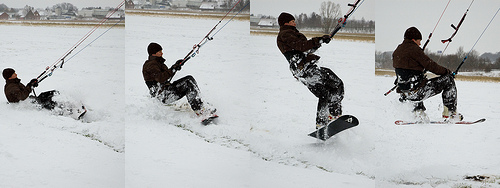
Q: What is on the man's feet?
A: Snowboard.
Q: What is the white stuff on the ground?
A: Snow.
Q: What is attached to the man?
A: Harness.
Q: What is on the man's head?
A: Hat.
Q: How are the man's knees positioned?
A: Bent.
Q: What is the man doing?
A: Snowboarding.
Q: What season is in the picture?
A: Winter.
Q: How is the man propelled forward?
A: Gravity and a kite.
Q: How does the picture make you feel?
A: Excited.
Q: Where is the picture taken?
A: A ski resort.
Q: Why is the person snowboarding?
A: It's fun.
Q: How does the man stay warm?
A: A snowsuit.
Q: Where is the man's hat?
A: On his head.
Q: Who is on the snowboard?
A: A man.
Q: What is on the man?
A: Snow.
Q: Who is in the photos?
A: The same man.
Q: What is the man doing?
A: Snowboarding.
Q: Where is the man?
A: In the air.